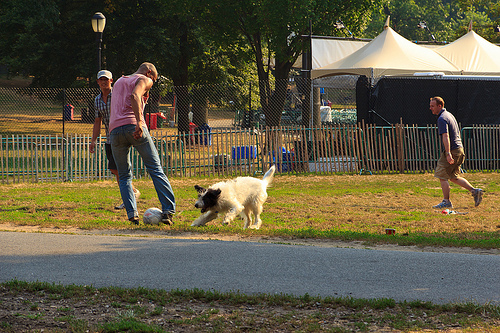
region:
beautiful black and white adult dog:
[175, 148, 317, 233]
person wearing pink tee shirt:
[92, 52, 191, 232]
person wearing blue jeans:
[91, 38, 183, 240]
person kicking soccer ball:
[96, 50, 181, 245]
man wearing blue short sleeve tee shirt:
[426, 91, 477, 214]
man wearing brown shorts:
[417, 85, 484, 214]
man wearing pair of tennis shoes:
[426, 87, 487, 229]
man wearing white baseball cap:
[71, 56, 126, 162]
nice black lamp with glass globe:
[51, 8, 118, 194]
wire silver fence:
[16, 110, 485, 184]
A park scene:
[0, 0, 499, 328]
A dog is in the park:
[188, 164, 278, 231]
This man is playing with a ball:
[105, 61, 178, 228]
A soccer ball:
[141, 205, 163, 226]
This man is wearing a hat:
[94, 67, 114, 92]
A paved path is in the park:
[0, 222, 497, 304]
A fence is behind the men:
[0, 123, 499, 183]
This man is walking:
[426, 93, 485, 213]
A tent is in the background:
[303, 13, 498, 173]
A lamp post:
[88, 8, 110, 69]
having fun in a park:
[50, 19, 480, 249]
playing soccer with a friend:
[75, 66, 195, 225]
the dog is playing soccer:
[110, 61, 278, 235]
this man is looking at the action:
[395, 93, 492, 218]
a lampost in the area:
[82, 10, 117, 62]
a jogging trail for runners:
[13, 214, 477, 329]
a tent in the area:
[320, 23, 495, 133]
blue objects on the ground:
[200, 129, 320, 170]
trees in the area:
[180, 20, 300, 110]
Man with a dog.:
[101, 41, 369, 261]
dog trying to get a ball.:
[129, 162, 314, 252]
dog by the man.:
[103, 121, 380, 290]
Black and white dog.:
[163, 154, 317, 254]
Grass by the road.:
[230, 193, 456, 309]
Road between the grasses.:
[141, 207, 301, 310]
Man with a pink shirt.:
[63, 47, 268, 225]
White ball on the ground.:
[132, 187, 174, 243]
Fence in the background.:
[163, 86, 285, 178]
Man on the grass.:
[412, 84, 495, 245]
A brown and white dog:
[188, 166, 277, 225]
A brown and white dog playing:
[190, 166, 282, 233]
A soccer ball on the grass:
[133, 197, 175, 231]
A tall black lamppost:
[85, 6, 109, 70]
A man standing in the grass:
[424, 89, 487, 216]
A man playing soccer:
[111, 52, 183, 230]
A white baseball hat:
[89, 63, 117, 80]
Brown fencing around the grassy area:
[268, 120, 420, 173]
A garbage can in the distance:
[61, 101, 74, 121]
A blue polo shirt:
[430, 107, 469, 150]